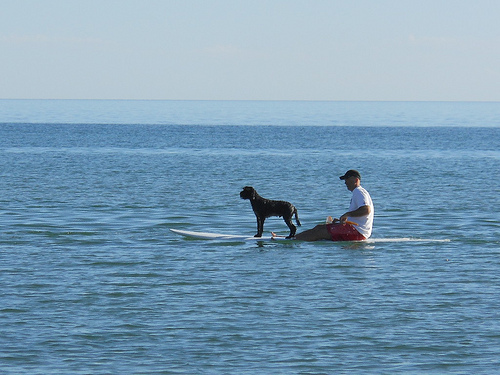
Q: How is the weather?
A: It is clear.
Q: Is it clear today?
A: Yes, it is clear.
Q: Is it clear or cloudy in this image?
A: It is clear.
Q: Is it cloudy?
A: No, it is clear.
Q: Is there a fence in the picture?
A: No, there are no fences.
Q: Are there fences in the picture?
A: No, there are no fences.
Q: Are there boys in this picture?
A: No, there are no boys.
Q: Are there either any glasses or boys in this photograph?
A: No, there are no boys or glasses.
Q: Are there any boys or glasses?
A: No, there are no boys or glasses.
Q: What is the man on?
A: The man is on the surfboard.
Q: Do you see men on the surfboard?
A: Yes, there is a man on the surfboard.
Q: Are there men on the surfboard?
A: Yes, there is a man on the surfboard.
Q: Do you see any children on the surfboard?
A: No, there is a man on the surfboard.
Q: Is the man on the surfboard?
A: Yes, the man is on the surfboard.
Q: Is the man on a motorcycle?
A: No, the man is on the surfboard.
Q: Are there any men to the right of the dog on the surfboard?
A: Yes, there is a man to the right of the dog.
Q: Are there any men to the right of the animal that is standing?
A: Yes, there is a man to the right of the dog.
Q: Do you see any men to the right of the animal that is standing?
A: Yes, there is a man to the right of the dog.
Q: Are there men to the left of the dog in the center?
A: No, the man is to the right of the dog.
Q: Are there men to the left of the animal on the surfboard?
A: No, the man is to the right of the dog.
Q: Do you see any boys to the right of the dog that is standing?
A: No, there is a man to the right of the dog.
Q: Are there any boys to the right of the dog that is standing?
A: No, there is a man to the right of the dog.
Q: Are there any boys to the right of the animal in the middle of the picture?
A: No, there is a man to the right of the dog.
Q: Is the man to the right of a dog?
A: Yes, the man is to the right of a dog.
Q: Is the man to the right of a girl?
A: No, the man is to the right of a dog.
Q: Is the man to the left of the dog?
A: No, the man is to the right of the dog.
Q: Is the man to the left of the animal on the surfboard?
A: No, the man is to the right of the dog.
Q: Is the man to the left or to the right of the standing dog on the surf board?
A: The man is to the right of the dog.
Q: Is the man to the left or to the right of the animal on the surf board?
A: The man is to the right of the dog.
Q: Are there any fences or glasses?
A: No, there are no fences or glasses.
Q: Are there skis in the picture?
A: No, there are no skis.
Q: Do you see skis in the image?
A: No, there are no skis.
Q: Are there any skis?
A: No, there are no skis.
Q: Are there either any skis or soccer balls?
A: No, there are no skis or soccer balls.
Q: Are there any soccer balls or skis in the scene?
A: No, there are no skis or soccer balls.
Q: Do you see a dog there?
A: Yes, there is a dog.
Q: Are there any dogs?
A: Yes, there is a dog.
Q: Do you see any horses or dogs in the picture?
A: Yes, there is a dog.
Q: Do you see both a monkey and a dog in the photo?
A: No, there is a dog but no monkeys.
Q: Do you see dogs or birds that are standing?
A: Yes, the dog is standing.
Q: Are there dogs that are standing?
A: Yes, there is a dog that is standing.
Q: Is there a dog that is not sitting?
A: Yes, there is a dog that is standing.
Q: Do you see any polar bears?
A: No, there are no polar bears.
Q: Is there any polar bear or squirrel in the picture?
A: No, there are no polar bears or squirrels.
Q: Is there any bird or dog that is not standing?
A: No, there is a dog but it is standing.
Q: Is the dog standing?
A: Yes, the dog is standing.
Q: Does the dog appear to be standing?
A: Yes, the dog is standing.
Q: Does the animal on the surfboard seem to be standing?
A: Yes, the dog is standing.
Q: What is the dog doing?
A: The dog is standing.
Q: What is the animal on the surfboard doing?
A: The dog is standing.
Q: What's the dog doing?
A: The dog is standing.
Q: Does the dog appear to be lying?
A: No, the dog is standing.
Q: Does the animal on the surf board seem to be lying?
A: No, the dog is standing.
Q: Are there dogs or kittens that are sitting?
A: No, there is a dog but it is standing.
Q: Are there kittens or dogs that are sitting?
A: No, there is a dog but it is standing.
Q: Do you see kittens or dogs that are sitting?
A: No, there is a dog but it is standing.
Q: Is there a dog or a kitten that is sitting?
A: No, there is a dog but it is standing.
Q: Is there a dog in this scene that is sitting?
A: No, there is a dog but it is standing.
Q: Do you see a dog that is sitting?
A: No, there is a dog but it is standing.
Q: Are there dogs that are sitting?
A: No, there is a dog but it is standing.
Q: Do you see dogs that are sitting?
A: No, there is a dog but it is standing.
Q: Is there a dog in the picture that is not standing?
A: No, there is a dog but it is standing.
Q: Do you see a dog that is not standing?
A: No, there is a dog but it is standing.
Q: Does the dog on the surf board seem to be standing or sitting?
A: The dog is standing.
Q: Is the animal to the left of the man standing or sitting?
A: The dog is standing.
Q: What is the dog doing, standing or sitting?
A: The dog is standing.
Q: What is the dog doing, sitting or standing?
A: The dog is standing.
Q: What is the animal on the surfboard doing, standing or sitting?
A: The dog is standing.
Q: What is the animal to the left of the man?
A: The animal is a dog.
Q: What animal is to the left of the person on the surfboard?
A: The animal is a dog.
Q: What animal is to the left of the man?
A: The animal is a dog.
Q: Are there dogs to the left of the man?
A: Yes, there is a dog to the left of the man.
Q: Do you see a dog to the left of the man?
A: Yes, there is a dog to the left of the man.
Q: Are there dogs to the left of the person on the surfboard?
A: Yes, there is a dog to the left of the man.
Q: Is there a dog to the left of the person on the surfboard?
A: Yes, there is a dog to the left of the man.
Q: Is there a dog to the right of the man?
A: No, the dog is to the left of the man.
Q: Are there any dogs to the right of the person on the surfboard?
A: No, the dog is to the left of the man.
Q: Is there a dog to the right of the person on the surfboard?
A: No, the dog is to the left of the man.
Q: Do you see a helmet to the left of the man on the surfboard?
A: No, there is a dog to the left of the man.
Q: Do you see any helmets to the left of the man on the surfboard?
A: No, there is a dog to the left of the man.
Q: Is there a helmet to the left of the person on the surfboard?
A: No, there is a dog to the left of the man.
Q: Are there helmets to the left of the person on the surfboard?
A: No, there is a dog to the left of the man.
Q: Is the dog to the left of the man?
A: Yes, the dog is to the left of the man.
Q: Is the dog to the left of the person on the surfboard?
A: Yes, the dog is to the left of the man.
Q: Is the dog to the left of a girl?
A: No, the dog is to the left of the man.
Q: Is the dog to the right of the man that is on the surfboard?
A: No, the dog is to the left of the man.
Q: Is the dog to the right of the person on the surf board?
A: No, the dog is to the left of the man.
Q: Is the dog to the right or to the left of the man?
A: The dog is to the left of the man.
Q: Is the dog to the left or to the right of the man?
A: The dog is to the left of the man.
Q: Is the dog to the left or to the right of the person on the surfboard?
A: The dog is to the left of the man.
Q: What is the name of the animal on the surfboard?
A: The animal is a dog.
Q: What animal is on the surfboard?
A: The animal is a dog.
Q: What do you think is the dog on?
A: The dog is on the surf board.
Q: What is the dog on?
A: The dog is on the surf board.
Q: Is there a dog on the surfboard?
A: Yes, there is a dog on the surfboard.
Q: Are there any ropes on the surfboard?
A: No, there is a dog on the surfboard.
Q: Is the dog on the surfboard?
A: Yes, the dog is on the surfboard.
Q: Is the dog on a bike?
A: No, the dog is on the surfboard.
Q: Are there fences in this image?
A: No, there are no fences.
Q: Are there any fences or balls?
A: No, there are no fences or balls.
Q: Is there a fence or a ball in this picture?
A: No, there are no fences or balls.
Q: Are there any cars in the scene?
A: No, there are no cars.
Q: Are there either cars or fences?
A: No, there are no cars or fences.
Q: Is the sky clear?
A: Yes, the sky is clear.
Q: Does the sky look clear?
A: Yes, the sky is clear.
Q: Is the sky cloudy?
A: No, the sky is clear.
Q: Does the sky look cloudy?
A: No, the sky is clear.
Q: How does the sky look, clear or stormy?
A: The sky is clear.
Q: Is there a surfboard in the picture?
A: Yes, there is a surfboard.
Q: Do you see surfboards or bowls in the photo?
A: Yes, there is a surfboard.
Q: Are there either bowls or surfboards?
A: Yes, there is a surfboard.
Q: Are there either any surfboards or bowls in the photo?
A: Yes, there is a surfboard.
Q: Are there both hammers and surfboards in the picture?
A: No, there is a surfboard but no hammers.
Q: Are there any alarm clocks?
A: No, there are no alarm clocks.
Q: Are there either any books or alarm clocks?
A: No, there are no alarm clocks or books.